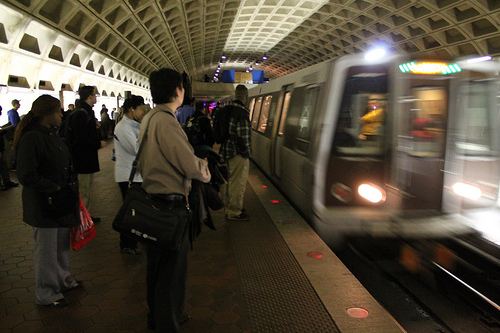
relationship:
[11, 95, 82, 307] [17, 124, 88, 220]
woman wearing coat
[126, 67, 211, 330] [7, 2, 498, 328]
person standing at train station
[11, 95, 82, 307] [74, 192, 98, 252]
woman holding red bag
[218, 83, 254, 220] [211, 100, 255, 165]
man in shirt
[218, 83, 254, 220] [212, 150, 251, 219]
man with pants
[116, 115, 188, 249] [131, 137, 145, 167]
bag with strap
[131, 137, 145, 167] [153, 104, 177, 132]
strap on shoulder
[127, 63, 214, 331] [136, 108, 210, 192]
man wearing coat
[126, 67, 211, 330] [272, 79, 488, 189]
person standing in train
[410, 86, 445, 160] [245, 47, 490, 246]
window on train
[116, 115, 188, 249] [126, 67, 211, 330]
bag on person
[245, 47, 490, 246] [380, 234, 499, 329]
train on tracks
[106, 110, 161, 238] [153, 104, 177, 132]
bag hanging on shoulder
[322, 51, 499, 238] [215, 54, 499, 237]
front end of train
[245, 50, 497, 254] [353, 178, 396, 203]
lights on train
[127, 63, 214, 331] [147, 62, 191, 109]
man has hair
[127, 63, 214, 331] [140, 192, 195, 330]
man wearing pants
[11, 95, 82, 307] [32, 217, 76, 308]
woman wearing pants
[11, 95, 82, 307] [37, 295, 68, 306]
woman wearing shoe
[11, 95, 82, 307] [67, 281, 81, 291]
woman wearing shoe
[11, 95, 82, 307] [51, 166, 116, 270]
woman holdinh red bag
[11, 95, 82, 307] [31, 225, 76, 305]
woman wearing pants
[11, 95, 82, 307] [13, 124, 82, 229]
woman wearing coat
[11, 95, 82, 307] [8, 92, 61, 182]
woman has hair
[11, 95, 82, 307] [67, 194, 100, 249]
woman holding bag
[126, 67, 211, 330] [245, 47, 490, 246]
person next to train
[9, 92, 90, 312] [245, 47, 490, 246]
person next to train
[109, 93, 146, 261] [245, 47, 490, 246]
person next to train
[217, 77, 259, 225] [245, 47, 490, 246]
person next to train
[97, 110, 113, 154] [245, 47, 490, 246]
person next to train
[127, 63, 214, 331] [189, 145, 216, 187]
man carrying a bag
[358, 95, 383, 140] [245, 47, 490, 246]
passenger aboard train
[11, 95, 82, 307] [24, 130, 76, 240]
woman wearing jacket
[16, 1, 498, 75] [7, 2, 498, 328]
ceiling of train station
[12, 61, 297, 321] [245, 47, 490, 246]
people waiting for train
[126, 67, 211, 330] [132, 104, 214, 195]
person in sweater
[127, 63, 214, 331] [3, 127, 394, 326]
man standing on platform